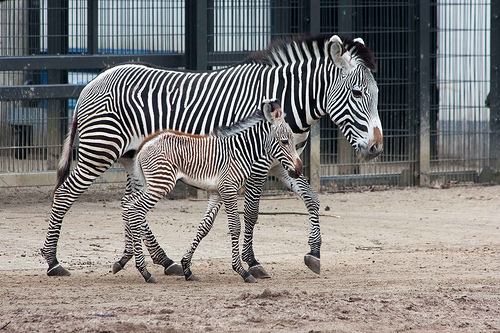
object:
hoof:
[301, 251, 324, 274]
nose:
[290, 157, 301, 177]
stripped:
[111, 77, 246, 115]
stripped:
[161, 143, 243, 172]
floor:
[0, 163, 499, 330]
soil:
[231, 281, 317, 311]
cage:
[3, 1, 498, 186]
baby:
[113, 99, 300, 285]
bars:
[0, 45, 270, 105]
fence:
[2, 1, 499, 200]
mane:
[239, 32, 381, 76]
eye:
[280, 139, 290, 145]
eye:
[350, 88, 364, 97]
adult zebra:
[38, 28, 388, 275]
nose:
[357, 122, 388, 149]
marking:
[372, 125, 383, 143]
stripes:
[44, 36, 378, 174]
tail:
[131, 136, 150, 190]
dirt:
[0, 182, 500, 331]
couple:
[40, 34, 384, 283]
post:
[415, 2, 437, 191]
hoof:
[302, 256, 323, 276]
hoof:
[250, 261, 268, 278]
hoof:
[166, 262, 181, 273]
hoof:
[108, 261, 121, 273]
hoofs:
[45, 265, 71, 279]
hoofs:
[145, 277, 159, 283]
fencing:
[438, 0, 490, 181]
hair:
[50, 128, 75, 204]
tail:
[53, 96, 78, 199]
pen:
[4, 7, 498, 328]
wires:
[445, 51, 464, 112]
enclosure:
[22, 50, 498, 292]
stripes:
[234, 132, 264, 173]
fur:
[56, 188, 76, 200]